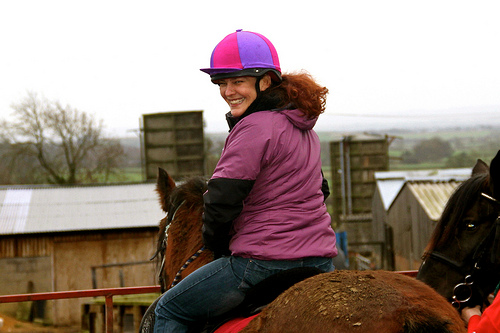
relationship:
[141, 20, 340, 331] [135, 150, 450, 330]
girl riding horse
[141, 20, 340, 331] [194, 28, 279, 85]
girl wearing helmet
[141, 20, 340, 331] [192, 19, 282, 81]
girl wearing helmet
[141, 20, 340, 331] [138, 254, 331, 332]
girl wearing blue jeans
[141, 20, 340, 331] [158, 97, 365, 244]
girl wearing hoodie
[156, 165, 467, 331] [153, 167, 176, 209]
horse has ear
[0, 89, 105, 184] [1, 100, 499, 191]
tree in background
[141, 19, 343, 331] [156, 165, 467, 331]
girl sitting on horse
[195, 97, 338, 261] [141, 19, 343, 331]
hoodie on girl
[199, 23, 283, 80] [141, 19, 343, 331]
hat on girl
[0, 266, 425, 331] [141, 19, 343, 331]
metal rail on girl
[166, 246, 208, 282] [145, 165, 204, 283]
harness on face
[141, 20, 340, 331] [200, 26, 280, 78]
girl on helmet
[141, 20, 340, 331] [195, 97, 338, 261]
girl on hoodie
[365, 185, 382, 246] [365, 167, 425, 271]
barn on buildings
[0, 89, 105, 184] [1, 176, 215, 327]
tree on barn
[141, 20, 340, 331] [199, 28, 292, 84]
girl on hat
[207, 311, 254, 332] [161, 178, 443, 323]
saddle on horse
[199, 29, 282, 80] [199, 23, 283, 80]
hat of hat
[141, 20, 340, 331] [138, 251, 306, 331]
girl wearing blue jeans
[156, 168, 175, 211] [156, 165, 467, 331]
ear of horse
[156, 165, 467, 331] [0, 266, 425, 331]
horse next to metal rail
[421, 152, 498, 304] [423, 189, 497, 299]
face of horse